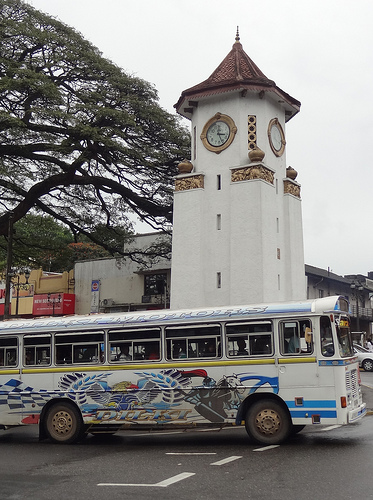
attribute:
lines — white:
[178, 444, 273, 481]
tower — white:
[175, 59, 327, 291]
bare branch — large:
[61, 174, 160, 224]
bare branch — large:
[51, 222, 116, 252]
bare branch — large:
[32, 152, 66, 170]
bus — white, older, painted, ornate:
[0, 293, 370, 449]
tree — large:
[0, 1, 192, 322]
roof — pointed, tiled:
[85, 248, 133, 266]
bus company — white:
[5, 306, 267, 326]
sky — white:
[24, 0, 371, 270]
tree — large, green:
[0, 1, 192, 275]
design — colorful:
[2, 368, 339, 417]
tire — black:
[41, 401, 81, 442]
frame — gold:
[227, 108, 242, 138]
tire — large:
[245, 403, 294, 446]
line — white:
[101, 267, 163, 283]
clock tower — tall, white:
[170, 24, 306, 309]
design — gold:
[247, 114, 259, 150]